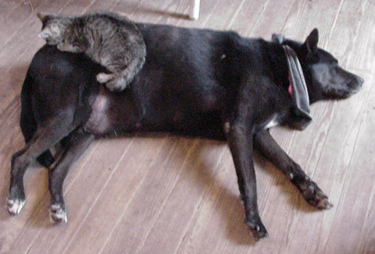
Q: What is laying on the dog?
A: Cat.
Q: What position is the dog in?
A: Lying.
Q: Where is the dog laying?
A: Floor.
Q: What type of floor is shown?
A: Hardwood.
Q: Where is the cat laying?
A: Back part of the dog.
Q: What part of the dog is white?
A: Tip of dog's feet.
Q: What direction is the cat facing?
A: Left.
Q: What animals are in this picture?
A: Dog and cat.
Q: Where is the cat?
A: On top of the dog.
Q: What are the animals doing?
A: Sleeping.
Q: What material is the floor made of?
A: Wood.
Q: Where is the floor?
A: Under the dog.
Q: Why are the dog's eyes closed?
A: It is asleep.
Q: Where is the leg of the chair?
A: Behind the dog.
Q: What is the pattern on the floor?
A: Stripes.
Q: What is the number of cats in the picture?
A: One.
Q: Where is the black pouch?
A: Around the dog's neck.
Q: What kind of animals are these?
A: Cat and dog.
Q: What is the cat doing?
A: Sitting on the dog.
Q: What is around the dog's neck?
A: Dog collar.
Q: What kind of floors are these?
A: Hardwood floors.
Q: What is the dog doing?
A: Lying down on the floor.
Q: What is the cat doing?
A: Lying down on the dog.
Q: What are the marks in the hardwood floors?
A: Striation marks.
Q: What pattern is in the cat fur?
A: Stripes.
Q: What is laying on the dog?
A: A cat.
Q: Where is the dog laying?
A: Floor.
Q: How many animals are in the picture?
A: Two.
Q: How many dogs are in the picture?
A: One.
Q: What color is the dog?
A: Black.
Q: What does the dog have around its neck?
A: Bandana.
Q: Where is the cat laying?
A: On the dog.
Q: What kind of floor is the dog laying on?
A: Wood.